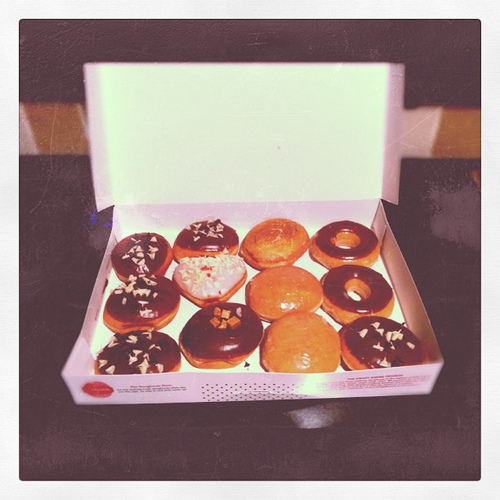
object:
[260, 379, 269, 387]
dots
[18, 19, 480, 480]
countertop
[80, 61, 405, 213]
lid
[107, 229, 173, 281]
donut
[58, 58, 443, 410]
box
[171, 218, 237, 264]
donut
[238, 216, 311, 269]
donut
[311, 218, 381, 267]
donut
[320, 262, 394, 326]
donut